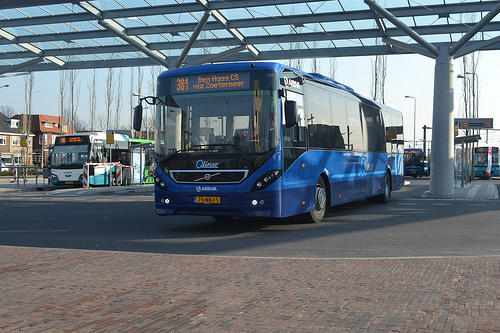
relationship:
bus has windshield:
[127, 39, 395, 228] [146, 89, 283, 161]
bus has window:
[127, 39, 395, 228] [274, 87, 355, 126]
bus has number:
[127, 39, 395, 228] [161, 66, 209, 98]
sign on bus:
[171, 61, 253, 109] [127, 39, 395, 228]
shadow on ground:
[191, 220, 245, 248] [140, 233, 244, 288]